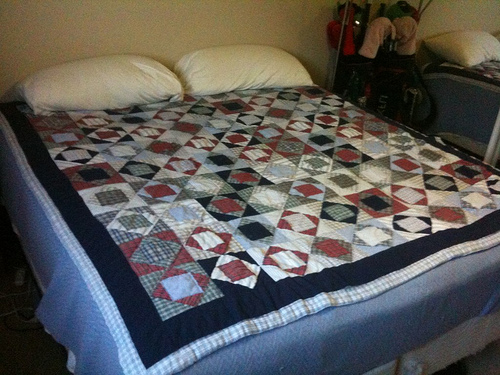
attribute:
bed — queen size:
[1, 42, 499, 373]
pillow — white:
[19, 49, 182, 113]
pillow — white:
[171, 42, 316, 100]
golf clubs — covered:
[330, 17, 375, 93]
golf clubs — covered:
[324, 4, 427, 107]